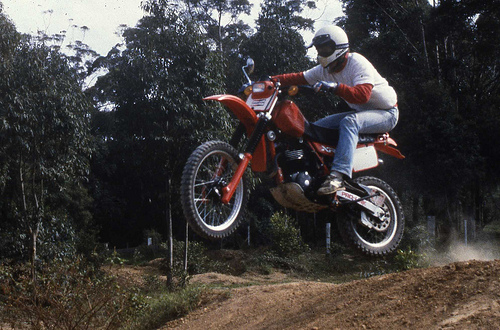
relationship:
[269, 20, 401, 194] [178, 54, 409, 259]
man racing motorcycle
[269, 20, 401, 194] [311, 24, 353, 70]
man wearing helmet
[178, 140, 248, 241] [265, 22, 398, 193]
tire on front of motorcycle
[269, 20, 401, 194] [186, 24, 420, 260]
man riding bike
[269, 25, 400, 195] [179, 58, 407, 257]
man jumping of ramp on bike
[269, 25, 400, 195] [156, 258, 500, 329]
man jumping off dirt ramp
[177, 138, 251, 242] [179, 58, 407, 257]
tire on front of bike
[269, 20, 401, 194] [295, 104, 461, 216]
man wearing jeans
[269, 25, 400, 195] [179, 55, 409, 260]
man on bike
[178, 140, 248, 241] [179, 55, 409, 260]
tire on bike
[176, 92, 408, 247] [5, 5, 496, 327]
bike in photo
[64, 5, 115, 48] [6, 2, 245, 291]
sky above trees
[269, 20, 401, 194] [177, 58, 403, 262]
man jumping motorcyle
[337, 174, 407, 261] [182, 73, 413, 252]
rear wheel of motorcycle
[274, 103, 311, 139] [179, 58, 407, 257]
tank of bike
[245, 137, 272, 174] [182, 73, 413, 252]
fender of motorcycle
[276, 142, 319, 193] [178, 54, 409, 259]
engine of motorcycle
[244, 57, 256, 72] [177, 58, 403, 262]
mirror on motorcyle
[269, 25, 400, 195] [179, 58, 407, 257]
man sitting on bike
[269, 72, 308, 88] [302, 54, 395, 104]
sleeve under shirt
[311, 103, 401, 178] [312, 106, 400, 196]
jeans on legs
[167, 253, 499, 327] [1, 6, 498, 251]
dirt ramp in forrest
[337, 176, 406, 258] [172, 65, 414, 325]
rear wheel mounted on bike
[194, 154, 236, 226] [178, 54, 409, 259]
spoke mounted on motorcycle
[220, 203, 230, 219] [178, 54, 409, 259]
spoke mounted on motorcycle